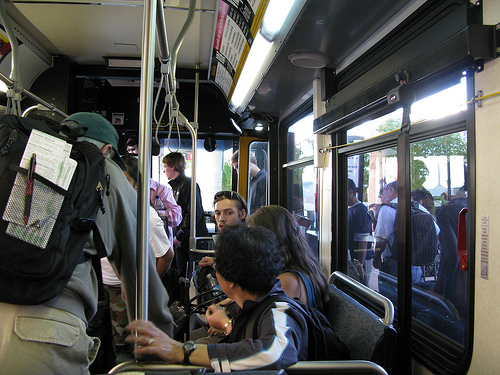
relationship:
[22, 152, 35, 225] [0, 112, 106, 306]
pen clipped to backpack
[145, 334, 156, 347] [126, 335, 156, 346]
ring on finger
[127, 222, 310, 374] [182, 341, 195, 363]
person wearing watch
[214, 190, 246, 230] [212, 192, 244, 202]
person with sunglasses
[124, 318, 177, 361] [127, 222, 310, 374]
hand of a person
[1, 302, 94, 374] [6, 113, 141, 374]
part of man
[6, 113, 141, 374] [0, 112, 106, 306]
man carrying backpack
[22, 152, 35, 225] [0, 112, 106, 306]
pen in backpack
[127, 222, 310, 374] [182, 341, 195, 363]
person wearing a watch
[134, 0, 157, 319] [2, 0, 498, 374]
pole in train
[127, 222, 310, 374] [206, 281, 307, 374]
person in jacket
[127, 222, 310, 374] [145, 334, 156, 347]
person wearing a ring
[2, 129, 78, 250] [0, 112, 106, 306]
paper in backpack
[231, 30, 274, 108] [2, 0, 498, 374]
light in train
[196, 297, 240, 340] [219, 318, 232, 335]
person wearing a bracelet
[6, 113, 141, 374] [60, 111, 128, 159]
man wearing hat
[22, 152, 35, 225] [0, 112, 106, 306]
pen on backpack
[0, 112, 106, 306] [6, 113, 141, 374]
backpack of man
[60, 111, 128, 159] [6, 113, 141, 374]
hat on man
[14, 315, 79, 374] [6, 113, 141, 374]
pocket of man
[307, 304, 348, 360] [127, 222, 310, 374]
backpack of person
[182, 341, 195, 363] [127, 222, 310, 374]
watch on person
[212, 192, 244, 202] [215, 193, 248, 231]
sunglasses on head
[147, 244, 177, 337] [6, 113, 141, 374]
sweatshirt of man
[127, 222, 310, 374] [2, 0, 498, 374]
person travels in train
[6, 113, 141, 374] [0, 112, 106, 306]
man holding backpack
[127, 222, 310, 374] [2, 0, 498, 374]
person sitting in train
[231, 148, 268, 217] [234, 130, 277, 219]
person in doorstep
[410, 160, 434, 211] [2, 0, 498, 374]
person outside train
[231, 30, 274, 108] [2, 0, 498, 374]
light on train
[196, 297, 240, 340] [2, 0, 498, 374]
person riding on train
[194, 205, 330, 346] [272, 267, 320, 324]
person in top